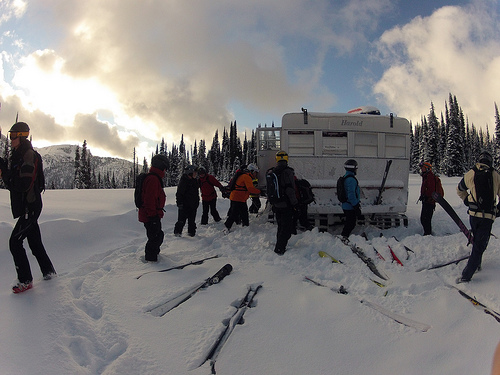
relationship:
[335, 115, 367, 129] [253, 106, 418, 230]
"harold" written on camper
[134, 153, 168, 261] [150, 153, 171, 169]
people have helmets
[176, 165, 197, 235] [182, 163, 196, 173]
people have helmets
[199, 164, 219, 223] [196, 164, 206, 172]
people have helmets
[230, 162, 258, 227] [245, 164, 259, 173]
people have helmets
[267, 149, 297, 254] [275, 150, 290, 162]
people have helmets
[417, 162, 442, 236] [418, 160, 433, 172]
people have helmets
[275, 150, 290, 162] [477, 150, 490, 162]
helmets have helmets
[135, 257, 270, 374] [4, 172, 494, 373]
skis are on ground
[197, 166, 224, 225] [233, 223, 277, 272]
people walking in snow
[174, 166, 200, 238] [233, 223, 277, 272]
people walking in snow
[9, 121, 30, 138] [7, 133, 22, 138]
helmet has goggles